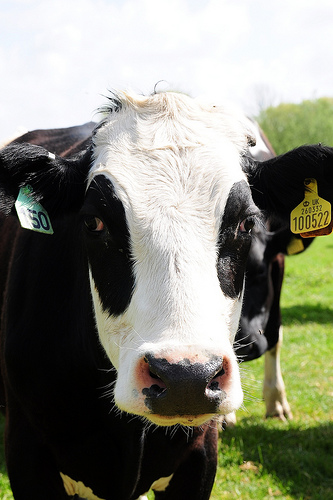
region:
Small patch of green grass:
[297, 353, 318, 376]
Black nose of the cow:
[171, 369, 196, 400]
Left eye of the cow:
[237, 211, 258, 240]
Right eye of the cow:
[86, 214, 104, 234]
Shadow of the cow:
[241, 429, 316, 456]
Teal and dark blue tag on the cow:
[13, 189, 52, 238]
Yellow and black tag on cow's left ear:
[288, 179, 331, 242]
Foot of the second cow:
[263, 371, 289, 425]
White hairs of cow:
[104, 389, 114, 401]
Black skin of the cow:
[23, 286, 66, 325]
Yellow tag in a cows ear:
[280, 175, 324, 253]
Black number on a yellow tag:
[285, 212, 297, 235]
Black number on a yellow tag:
[296, 213, 304, 233]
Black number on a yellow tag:
[304, 214, 312, 231]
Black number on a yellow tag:
[310, 207, 316, 230]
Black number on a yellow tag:
[315, 210, 321, 230]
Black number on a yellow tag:
[321, 206, 331, 228]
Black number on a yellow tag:
[298, 207, 324, 213]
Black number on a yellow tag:
[283, 211, 324, 233]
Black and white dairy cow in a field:
[10, 113, 262, 484]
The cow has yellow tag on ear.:
[280, 178, 325, 230]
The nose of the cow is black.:
[153, 370, 216, 412]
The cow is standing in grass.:
[20, 105, 285, 475]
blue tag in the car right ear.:
[13, 184, 69, 246]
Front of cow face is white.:
[144, 143, 215, 314]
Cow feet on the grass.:
[255, 364, 312, 434]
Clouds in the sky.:
[63, 9, 292, 83]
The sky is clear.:
[36, 15, 283, 90]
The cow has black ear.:
[21, 133, 81, 218]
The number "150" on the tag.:
[9, 199, 48, 243]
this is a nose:
[97, 329, 251, 407]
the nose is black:
[162, 329, 221, 485]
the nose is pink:
[154, 301, 237, 467]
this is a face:
[149, 304, 221, 383]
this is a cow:
[77, 322, 153, 400]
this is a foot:
[256, 351, 299, 447]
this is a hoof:
[268, 400, 279, 410]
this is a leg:
[255, 356, 279, 402]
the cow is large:
[24, 407, 71, 452]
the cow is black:
[55, 447, 110, 495]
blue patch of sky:
[6, 2, 19, 14]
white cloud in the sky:
[35, 7, 79, 32]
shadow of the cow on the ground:
[265, 441, 331, 474]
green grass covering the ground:
[291, 330, 317, 383]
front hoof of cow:
[263, 386, 294, 419]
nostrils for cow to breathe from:
[135, 343, 231, 411]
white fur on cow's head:
[151, 205, 203, 332]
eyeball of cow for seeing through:
[239, 211, 257, 231]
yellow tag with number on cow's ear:
[290, 179, 330, 237]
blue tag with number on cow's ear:
[13, 183, 58, 233]